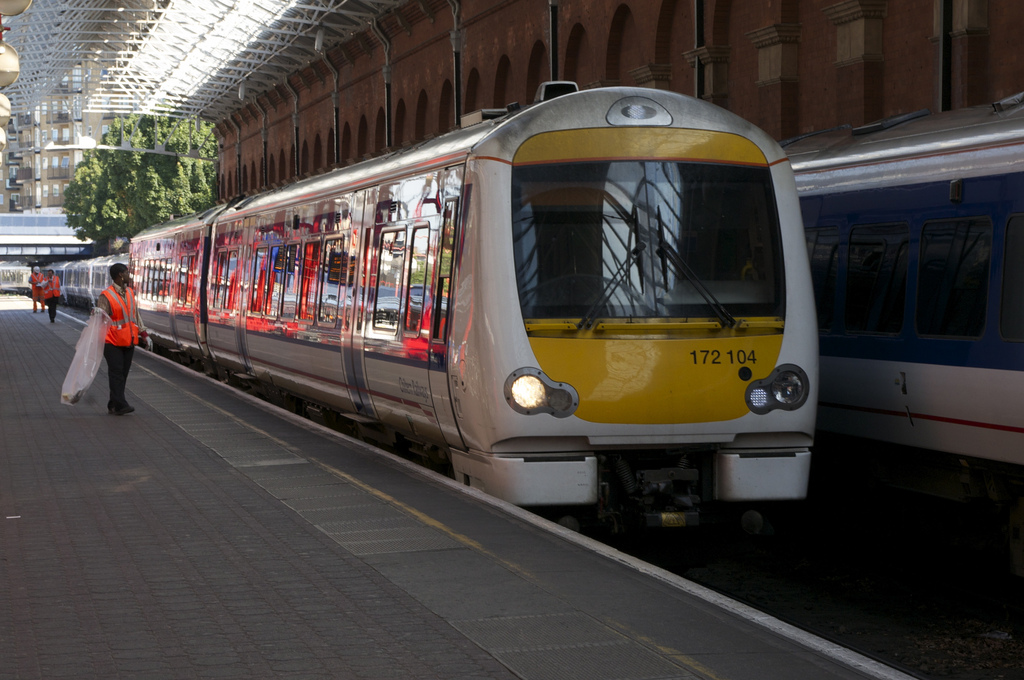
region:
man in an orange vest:
[96, 259, 153, 416]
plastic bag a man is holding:
[58, 305, 115, 407]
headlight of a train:
[504, 370, 553, 413]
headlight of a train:
[750, 344, 811, 420]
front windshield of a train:
[511, 128, 780, 328]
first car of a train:
[210, 80, 820, 514]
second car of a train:
[124, 202, 205, 361]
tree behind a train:
[56, 102, 225, 223]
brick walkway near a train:
[2, 300, 530, 675]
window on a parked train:
[374, 213, 401, 335]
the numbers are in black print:
[686, 347, 760, 367]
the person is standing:
[98, 260, 141, 416]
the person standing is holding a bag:
[62, 262, 143, 417]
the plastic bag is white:
[59, 303, 111, 403]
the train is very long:
[8, 79, 818, 514]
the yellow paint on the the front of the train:
[0, 88, 822, 529]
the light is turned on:
[512, 372, 544, 408]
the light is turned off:
[773, 367, 806, 406]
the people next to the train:
[1, 79, 823, 529]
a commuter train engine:
[204, 82, 818, 541]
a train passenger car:
[124, 203, 217, 369]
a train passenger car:
[64, 251, 96, 312]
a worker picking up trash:
[58, 262, 145, 418]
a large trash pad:
[59, 308, 104, 408]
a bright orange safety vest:
[102, 281, 140, 346]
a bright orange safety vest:
[39, 273, 63, 302]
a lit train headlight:
[510, 377, 546, 407]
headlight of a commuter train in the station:
[502, 361, 580, 419]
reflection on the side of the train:
[136, 164, 466, 357]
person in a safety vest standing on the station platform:
[57, 262, 143, 421]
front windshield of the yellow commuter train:
[506, 151, 779, 320]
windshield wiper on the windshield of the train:
[574, 228, 645, 339]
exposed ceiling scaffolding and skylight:
[0, 2, 343, 126]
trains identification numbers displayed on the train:
[680, 338, 763, 370]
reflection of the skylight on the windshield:
[584, 155, 698, 320]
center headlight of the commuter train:
[607, 92, 677, 132]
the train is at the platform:
[19, 62, 1013, 672]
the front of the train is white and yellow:
[445, 79, 820, 517]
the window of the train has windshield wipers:
[515, 161, 781, 346]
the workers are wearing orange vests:
[8, 240, 173, 438]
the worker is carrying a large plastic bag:
[56, 259, 154, 416]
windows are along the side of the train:
[107, 214, 447, 361]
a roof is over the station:
[10, 0, 364, 191]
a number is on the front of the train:
[683, 338, 769, 376]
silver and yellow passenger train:
[189, 109, 812, 498]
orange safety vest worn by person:
[90, 280, 133, 345]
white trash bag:
[71, 309, 128, 393]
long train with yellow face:
[14, 67, 834, 530]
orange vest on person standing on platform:
[90, 279, 147, 353]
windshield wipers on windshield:
[566, 197, 743, 344]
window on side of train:
[394, 219, 434, 337]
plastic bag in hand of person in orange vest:
[52, 298, 106, 415]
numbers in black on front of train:
[675, 341, 762, 374]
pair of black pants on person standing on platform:
[93, 336, 136, 404]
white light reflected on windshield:
[593, 156, 691, 319]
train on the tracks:
[29, 81, 865, 538]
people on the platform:
[21, 238, 168, 385]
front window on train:
[527, 141, 790, 353]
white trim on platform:
[581, 519, 867, 676]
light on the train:
[497, 361, 583, 422]